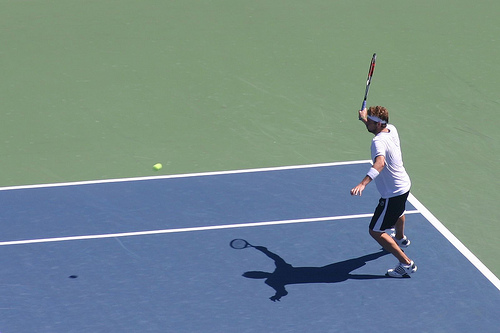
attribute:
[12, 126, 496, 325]
court — blue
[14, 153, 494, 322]
court — blue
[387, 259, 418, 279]
tennis shoe — white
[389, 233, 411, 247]
tennis shoe — white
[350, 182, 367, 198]
left hand — open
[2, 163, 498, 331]
tennis court — blue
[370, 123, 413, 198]
shirt — white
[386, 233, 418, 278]
tennis shoes — white